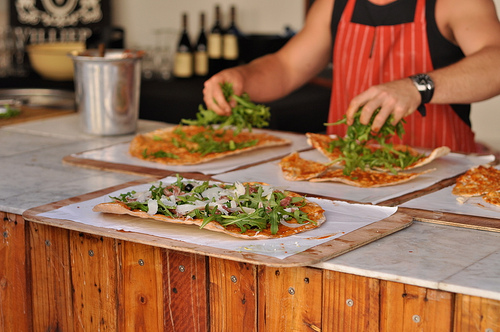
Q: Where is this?
A: This is at the kitchen.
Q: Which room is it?
A: It is a kitchen.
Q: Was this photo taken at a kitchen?
A: Yes, it was taken in a kitchen.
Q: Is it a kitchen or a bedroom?
A: It is a kitchen.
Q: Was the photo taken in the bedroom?
A: No, the picture was taken in the kitchen.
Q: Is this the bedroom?
A: No, it is the kitchen.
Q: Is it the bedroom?
A: No, it is the kitchen.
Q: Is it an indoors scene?
A: Yes, it is indoors.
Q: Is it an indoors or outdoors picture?
A: It is indoors.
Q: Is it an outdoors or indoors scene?
A: It is indoors.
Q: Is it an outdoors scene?
A: No, it is indoors.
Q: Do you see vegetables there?
A: Yes, there are vegetables.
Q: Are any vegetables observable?
A: Yes, there are vegetables.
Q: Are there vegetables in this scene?
A: Yes, there are vegetables.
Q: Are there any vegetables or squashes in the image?
A: Yes, there are vegetables.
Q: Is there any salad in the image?
A: No, there is no salad.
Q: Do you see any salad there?
A: No, there is no salad.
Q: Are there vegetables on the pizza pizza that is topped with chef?
A: Yes, there are vegetables on the pizza.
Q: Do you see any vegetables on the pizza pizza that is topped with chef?
A: Yes, there are vegetables on the pizza.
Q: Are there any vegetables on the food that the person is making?
A: Yes, there are vegetables on the pizza.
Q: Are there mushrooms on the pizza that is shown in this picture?
A: No, there are vegetables on the pizza.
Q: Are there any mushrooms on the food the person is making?
A: No, there are vegetables on the pizza.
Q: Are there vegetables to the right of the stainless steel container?
A: Yes, there are vegetables to the right of the container.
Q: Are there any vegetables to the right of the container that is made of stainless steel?
A: Yes, there are vegetables to the right of the container.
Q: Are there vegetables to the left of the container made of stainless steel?
A: No, the vegetables are to the right of the container.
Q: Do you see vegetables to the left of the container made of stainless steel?
A: No, the vegetables are to the right of the container.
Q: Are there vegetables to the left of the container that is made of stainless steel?
A: No, the vegetables are to the right of the container.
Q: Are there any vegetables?
A: Yes, there are vegetables.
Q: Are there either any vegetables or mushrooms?
A: Yes, there are vegetables.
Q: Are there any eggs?
A: No, there are no eggs.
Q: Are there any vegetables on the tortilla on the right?
A: Yes, there are vegetables on the tortilla.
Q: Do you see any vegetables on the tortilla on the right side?
A: Yes, there are vegetables on the tortilla.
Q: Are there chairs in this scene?
A: No, there are no chairs.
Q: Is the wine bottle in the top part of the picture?
A: Yes, the wine bottle is in the top of the image.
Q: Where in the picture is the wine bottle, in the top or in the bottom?
A: The wine bottle is in the top of the image.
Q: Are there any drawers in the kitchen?
A: No, there is a wine bottle in the kitchen.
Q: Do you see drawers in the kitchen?
A: No, there is a wine bottle in the kitchen.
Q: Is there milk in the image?
A: No, there is no milk.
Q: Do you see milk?
A: No, there is no milk.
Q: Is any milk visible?
A: No, there is no milk.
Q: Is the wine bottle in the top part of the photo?
A: Yes, the wine bottle is in the top of the image.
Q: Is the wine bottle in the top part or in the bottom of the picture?
A: The wine bottle is in the top of the image.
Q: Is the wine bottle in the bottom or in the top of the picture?
A: The wine bottle is in the top of the image.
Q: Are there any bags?
A: No, there are no bags.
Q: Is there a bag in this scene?
A: No, there are no bags.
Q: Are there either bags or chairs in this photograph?
A: No, there are no bags or chairs.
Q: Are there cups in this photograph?
A: No, there are no cups.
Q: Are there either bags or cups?
A: No, there are no cups or bags.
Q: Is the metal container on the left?
A: Yes, the container is on the left of the image.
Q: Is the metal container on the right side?
A: No, the container is on the left of the image.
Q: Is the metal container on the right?
A: No, the container is on the left of the image.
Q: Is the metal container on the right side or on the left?
A: The container is on the left of the image.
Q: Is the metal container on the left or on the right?
A: The container is on the left of the image.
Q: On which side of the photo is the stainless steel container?
A: The container is on the left of the image.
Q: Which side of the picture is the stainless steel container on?
A: The container is on the left of the image.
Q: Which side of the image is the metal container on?
A: The container is on the left of the image.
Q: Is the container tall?
A: Yes, the container is tall.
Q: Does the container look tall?
A: Yes, the container is tall.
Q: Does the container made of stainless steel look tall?
A: Yes, the container is tall.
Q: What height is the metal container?
A: The container is tall.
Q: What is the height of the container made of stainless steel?
A: The container is tall.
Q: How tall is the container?
A: The container is tall.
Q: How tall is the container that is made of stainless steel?
A: The container is tall.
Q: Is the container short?
A: No, the container is tall.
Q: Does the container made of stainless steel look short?
A: No, the container is tall.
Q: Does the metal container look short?
A: No, the container is tall.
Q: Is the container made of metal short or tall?
A: The container is tall.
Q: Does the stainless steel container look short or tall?
A: The container is tall.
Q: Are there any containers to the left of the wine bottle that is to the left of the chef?
A: Yes, there is a container to the left of the wine bottle.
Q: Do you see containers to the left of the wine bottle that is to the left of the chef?
A: Yes, there is a container to the left of the wine bottle.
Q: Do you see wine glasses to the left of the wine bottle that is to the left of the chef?
A: No, there is a container to the left of the wine bottle.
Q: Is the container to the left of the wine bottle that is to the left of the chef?
A: Yes, the container is to the left of the wine bottle.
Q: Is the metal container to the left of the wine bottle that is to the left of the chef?
A: Yes, the container is to the left of the wine bottle.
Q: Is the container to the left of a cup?
A: No, the container is to the left of the wine bottle.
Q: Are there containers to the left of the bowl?
A: No, the container is to the right of the bowl.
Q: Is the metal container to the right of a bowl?
A: Yes, the container is to the right of a bowl.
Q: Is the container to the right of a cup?
A: No, the container is to the right of a bowl.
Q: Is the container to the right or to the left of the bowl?
A: The container is to the right of the bowl.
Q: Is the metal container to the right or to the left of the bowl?
A: The container is to the right of the bowl.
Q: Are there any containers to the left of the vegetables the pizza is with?
A: Yes, there is a container to the left of the veggies.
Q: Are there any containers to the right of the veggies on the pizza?
A: No, the container is to the left of the veggies.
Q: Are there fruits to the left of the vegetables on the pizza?
A: No, there is a container to the left of the vegetables.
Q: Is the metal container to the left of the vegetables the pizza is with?
A: Yes, the container is to the left of the vegetables.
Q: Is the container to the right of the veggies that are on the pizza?
A: No, the container is to the left of the veggies.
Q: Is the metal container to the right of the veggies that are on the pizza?
A: No, the container is to the left of the veggies.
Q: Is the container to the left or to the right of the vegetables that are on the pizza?
A: The container is to the left of the veggies.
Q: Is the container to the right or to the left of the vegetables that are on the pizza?
A: The container is to the left of the veggies.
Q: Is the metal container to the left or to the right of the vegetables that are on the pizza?
A: The container is to the left of the veggies.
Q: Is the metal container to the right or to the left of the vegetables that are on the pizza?
A: The container is to the left of the veggies.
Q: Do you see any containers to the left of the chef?
A: Yes, there is a container to the left of the chef.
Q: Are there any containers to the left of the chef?
A: Yes, there is a container to the left of the chef.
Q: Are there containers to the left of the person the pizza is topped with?
A: Yes, there is a container to the left of the chef.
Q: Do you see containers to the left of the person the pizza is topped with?
A: Yes, there is a container to the left of the chef.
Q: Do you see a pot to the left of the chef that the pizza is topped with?
A: No, there is a container to the left of the chef.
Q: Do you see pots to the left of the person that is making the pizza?
A: No, there is a container to the left of the chef.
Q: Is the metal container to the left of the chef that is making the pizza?
A: Yes, the container is to the left of the chef.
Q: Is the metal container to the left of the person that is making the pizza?
A: Yes, the container is to the left of the chef.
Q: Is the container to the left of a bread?
A: No, the container is to the left of the chef.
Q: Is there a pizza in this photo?
A: Yes, there is a pizza.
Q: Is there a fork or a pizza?
A: Yes, there is a pizza.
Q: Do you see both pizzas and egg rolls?
A: No, there is a pizza but no egg rolls.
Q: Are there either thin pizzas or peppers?
A: Yes, there is a thin pizza.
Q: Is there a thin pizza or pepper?
A: Yes, there is a thin pizza.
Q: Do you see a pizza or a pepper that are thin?
A: Yes, the pizza is thin.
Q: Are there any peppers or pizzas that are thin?
A: Yes, the pizza is thin.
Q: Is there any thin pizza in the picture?
A: Yes, there is a thin pizza.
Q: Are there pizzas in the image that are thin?
A: Yes, there is a pizza that is thin.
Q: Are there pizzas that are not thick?
A: Yes, there is a thin pizza.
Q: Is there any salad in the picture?
A: No, there is no salad.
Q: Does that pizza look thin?
A: Yes, the pizza is thin.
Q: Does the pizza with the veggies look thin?
A: Yes, the pizza is thin.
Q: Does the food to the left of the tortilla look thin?
A: Yes, the pizza is thin.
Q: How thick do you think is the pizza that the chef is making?
A: The pizza is thin.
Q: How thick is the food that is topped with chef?
A: The pizza is thin.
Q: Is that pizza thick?
A: No, the pizza is thin.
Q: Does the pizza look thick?
A: No, the pizza is thin.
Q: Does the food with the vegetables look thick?
A: No, the pizza is thin.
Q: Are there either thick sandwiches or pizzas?
A: No, there is a pizza but it is thin.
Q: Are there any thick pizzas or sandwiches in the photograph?
A: No, there is a pizza but it is thin.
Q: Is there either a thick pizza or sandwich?
A: No, there is a pizza but it is thin.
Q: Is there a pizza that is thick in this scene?
A: No, there is a pizza but it is thin.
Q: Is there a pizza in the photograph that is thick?
A: No, there is a pizza but it is thin.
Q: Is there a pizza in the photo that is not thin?
A: No, there is a pizza but it is thin.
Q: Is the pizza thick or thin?
A: The pizza is thin.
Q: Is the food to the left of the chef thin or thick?
A: The pizza is thin.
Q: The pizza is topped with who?
A: The pizza is topped with chef.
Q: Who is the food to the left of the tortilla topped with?
A: The pizza is topped with chef.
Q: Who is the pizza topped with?
A: The pizza is topped with chef.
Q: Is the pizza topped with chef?
A: Yes, the pizza is topped with chef.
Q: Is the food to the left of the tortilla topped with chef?
A: Yes, the pizza is topped with chef.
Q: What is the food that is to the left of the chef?
A: The food is a pizza.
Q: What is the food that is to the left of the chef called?
A: The food is a pizza.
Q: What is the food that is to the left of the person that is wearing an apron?
A: The food is a pizza.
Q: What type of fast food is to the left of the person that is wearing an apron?
A: The food is a pizza.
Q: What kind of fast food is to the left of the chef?
A: The food is a pizza.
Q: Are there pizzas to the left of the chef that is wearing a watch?
A: Yes, there is a pizza to the left of the chef.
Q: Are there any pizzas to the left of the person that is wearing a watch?
A: Yes, there is a pizza to the left of the chef.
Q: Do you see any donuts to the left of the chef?
A: No, there is a pizza to the left of the chef.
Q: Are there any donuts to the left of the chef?
A: No, there is a pizza to the left of the chef.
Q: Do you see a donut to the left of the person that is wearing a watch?
A: No, there is a pizza to the left of the chef.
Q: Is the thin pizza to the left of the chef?
A: Yes, the pizza is to the left of the chef.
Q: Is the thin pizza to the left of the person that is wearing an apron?
A: Yes, the pizza is to the left of the chef.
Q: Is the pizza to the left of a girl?
A: No, the pizza is to the left of the chef.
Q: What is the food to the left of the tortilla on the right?
A: The food is a pizza.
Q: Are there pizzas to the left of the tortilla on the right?
A: Yes, there is a pizza to the left of the tortilla.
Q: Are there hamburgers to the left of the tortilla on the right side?
A: No, there is a pizza to the left of the tortilla.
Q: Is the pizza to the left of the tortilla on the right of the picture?
A: Yes, the pizza is to the left of the tortilla.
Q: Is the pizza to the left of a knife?
A: No, the pizza is to the left of the tortilla.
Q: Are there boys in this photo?
A: No, there are no boys.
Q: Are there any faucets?
A: No, there are no faucets.